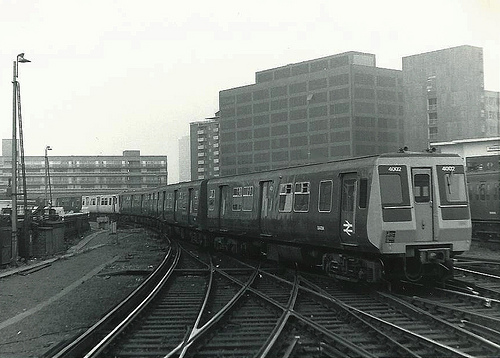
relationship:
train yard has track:
[2, 221, 497, 356] [42, 228, 500, 358]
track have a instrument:
[42, 228, 500, 358] [16, 53, 31, 63]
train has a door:
[55, 154, 471, 288] [412, 167, 435, 243]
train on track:
[55, 154, 471, 288] [42, 228, 500, 358]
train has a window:
[55, 154, 471, 288] [317, 180, 332, 213]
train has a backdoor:
[55, 154, 471, 288] [341, 173, 358, 244]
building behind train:
[402, 44, 500, 153] [55, 154, 471, 288]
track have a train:
[42, 228, 500, 358] [55, 154, 471, 288]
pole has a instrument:
[14, 51, 26, 267] [16, 53, 31, 63]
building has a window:
[402, 44, 500, 153] [427, 95, 436, 104]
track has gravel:
[42, 228, 499, 357] [2, 224, 169, 356]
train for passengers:
[55, 154, 471, 288] [280, 183, 312, 214]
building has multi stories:
[402, 44, 500, 153] [400, 78, 474, 95]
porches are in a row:
[429, 95, 437, 106] [424, 50, 439, 150]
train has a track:
[55, 154, 471, 288] [42, 228, 499, 357]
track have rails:
[42, 228, 500, 358] [52, 241, 182, 356]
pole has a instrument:
[14, 51, 26, 267] [19, 53, 32, 63]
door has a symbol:
[412, 167, 435, 243] [421, 218, 427, 230]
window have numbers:
[377, 175, 405, 206] [388, 165, 403, 173]